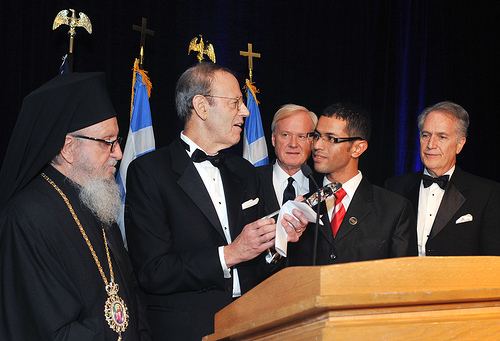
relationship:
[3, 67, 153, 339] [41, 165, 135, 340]
priest wearing necklace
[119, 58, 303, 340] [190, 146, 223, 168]
man wearing bowtie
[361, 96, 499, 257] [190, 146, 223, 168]
man wearing bowtie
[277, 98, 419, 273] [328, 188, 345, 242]
man in tie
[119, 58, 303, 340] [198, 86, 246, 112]
man wearing glasses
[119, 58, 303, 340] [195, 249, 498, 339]
man at podium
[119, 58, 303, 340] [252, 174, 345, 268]
man holding award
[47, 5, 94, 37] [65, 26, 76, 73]
eagle atop pole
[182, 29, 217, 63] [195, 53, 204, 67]
eagle atop pole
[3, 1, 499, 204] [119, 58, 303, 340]
curtain behind man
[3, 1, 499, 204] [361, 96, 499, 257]
curtain behind man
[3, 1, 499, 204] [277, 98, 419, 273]
curtain behind man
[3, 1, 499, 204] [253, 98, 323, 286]
curtain behind man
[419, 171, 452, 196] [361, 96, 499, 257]
bowtie of man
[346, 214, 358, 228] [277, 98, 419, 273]
pin on man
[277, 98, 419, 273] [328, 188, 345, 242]
man has tie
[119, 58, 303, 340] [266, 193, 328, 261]
man holding item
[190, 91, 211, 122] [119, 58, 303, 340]
ear of man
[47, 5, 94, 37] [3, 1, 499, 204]
eagle against curtain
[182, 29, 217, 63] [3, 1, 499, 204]
eagle against curtain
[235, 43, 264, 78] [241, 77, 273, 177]
cross above flag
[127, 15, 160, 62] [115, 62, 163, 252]
cross above flag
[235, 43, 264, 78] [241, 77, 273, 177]
cross atop flag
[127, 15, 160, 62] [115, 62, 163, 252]
cross atop flag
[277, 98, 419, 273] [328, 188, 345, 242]
man wearing tie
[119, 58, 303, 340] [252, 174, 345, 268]
man presenting award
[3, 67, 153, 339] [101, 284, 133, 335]
priest wearing medallion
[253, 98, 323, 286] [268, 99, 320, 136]
man has hair